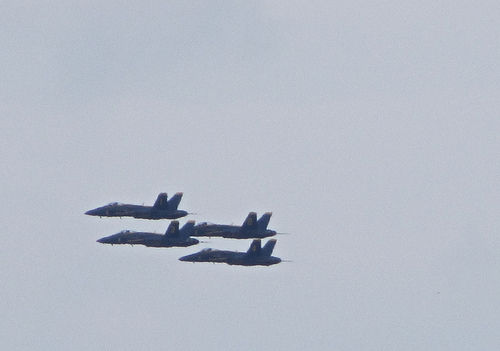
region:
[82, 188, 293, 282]
four jet planes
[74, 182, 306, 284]
jets in the sky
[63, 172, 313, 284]
black jet planes flying in sky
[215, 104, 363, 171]
grey cloudless sky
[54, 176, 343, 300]
four planes flying in grey sky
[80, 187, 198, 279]
two jet planes in the front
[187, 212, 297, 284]
two jet planes in the back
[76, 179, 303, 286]
four planes pointing left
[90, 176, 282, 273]
black jets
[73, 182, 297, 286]
four black jets pointing left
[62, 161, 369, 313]
four fighter planes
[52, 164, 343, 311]
blue angles precision flying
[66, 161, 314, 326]
experienced Navy pilots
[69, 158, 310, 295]
four blue jets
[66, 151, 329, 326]
four airplanes in flight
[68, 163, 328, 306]
jet planes in formation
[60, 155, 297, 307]
blue and yellow painted planes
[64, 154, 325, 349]
jets flying close together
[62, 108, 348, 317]
jets flying in a clear blue sky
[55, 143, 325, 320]
a group of jet planes in formation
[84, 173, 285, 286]
four planes in the sky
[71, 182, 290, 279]
planes flying in formation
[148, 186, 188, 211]
sharp wings of the plane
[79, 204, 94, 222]
pointed nose of the plane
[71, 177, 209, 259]
two planes flying parallel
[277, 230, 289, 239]
stream coming out of the back of the plane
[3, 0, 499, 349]
gray sky with no clouds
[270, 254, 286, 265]
back end of the plane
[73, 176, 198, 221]
plane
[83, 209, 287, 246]
plane flying close behind another plane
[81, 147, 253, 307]
Four planes are visible.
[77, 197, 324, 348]
Four planes are visible.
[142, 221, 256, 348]
Four planes are visible.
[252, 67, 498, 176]
this is the sky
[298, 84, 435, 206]
the sky is full of clouds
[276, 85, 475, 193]
the clouds are white in color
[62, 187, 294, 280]
these are four jets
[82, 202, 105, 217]
the front is sharp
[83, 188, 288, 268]
the jets are small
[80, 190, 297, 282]
the jets are in the air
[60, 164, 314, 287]
the jets are close together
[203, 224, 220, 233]
the jet is blue in color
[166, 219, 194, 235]
this is the back